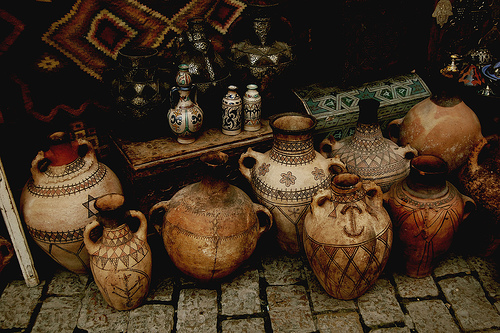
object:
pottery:
[165, 211, 258, 280]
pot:
[303, 174, 394, 302]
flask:
[167, 65, 205, 145]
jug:
[238, 113, 349, 258]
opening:
[269, 112, 318, 132]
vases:
[83, 193, 153, 311]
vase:
[383, 156, 478, 279]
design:
[406, 208, 445, 278]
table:
[107, 114, 271, 197]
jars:
[452, 54, 489, 90]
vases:
[174, 36, 237, 121]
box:
[288, 70, 433, 150]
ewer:
[221, 85, 243, 136]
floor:
[0, 255, 499, 331]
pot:
[109, 47, 177, 141]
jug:
[20, 132, 124, 276]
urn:
[20, 131, 124, 275]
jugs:
[242, 84, 262, 131]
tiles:
[266, 285, 319, 332]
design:
[42, 0, 170, 82]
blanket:
[0, 0, 314, 124]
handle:
[462, 196, 477, 222]